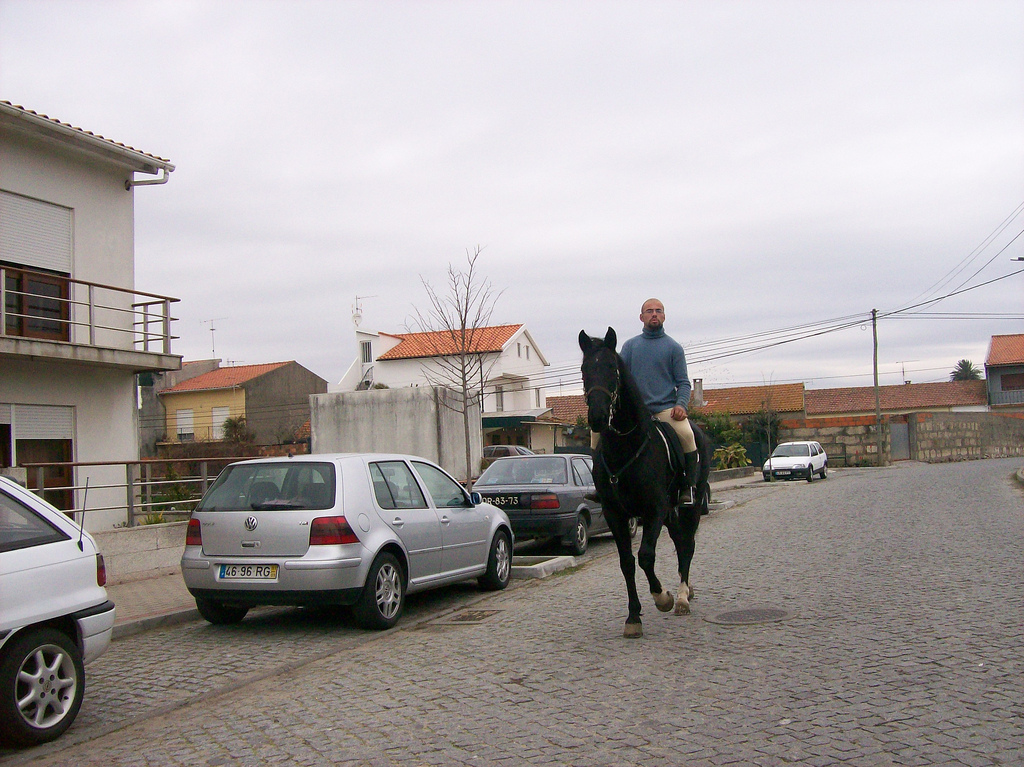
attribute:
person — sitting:
[617, 295, 707, 505]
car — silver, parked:
[182, 453, 512, 631]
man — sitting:
[620, 295, 700, 514]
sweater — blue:
[617, 330, 694, 407]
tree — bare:
[411, 244, 513, 494]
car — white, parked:
[762, 434, 829, 482]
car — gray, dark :
[473, 449, 622, 551]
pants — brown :
[643, 403, 698, 452]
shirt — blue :
[615, 325, 680, 415]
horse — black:
[482, 230, 781, 663]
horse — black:
[572, 320, 715, 640]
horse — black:
[572, 330, 707, 646]